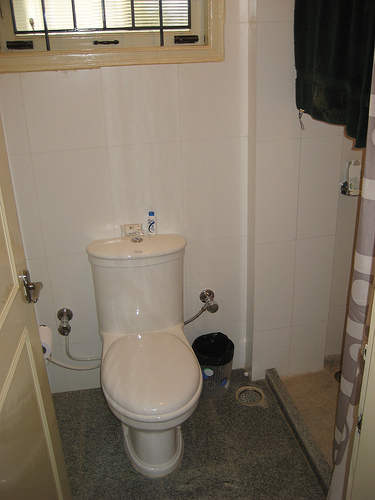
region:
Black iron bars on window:
[7, 0, 192, 34]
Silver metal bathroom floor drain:
[234, 385, 269, 410]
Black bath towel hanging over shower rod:
[294, 0, 373, 149]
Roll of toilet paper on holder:
[37, 323, 53, 357]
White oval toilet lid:
[100, 331, 199, 417]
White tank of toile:
[85, 233, 186, 327]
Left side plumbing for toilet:
[184, 288, 219, 326]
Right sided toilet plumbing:
[54, 307, 100, 362]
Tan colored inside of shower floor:
[281, 355, 348, 469]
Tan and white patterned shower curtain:
[327, 56, 374, 499]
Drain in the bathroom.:
[231, 382, 267, 412]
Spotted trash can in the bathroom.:
[193, 332, 246, 398]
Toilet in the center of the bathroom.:
[71, 224, 218, 488]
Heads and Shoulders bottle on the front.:
[141, 204, 162, 236]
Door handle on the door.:
[21, 271, 53, 313]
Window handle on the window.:
[90, 35, 126, 49]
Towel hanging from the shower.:
[297, 0, 368, 153]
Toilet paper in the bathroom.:
[40, 316, 55, 358]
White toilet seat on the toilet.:
[105, 331, 199, 416]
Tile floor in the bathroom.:
[222, 431, 273, 498]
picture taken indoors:
[36, 72, 313, 498]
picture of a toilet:
[41, 147, 247, 449]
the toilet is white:
[97, 227, 195, 472]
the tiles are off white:
[55, 103, 200, 181]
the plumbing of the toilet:
[54, 306, 94, 378]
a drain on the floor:
[236, 374, 272, 412]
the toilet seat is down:
[90, 325, 208, 413]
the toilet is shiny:
[123, 241, 155, 350]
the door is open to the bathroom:
[16, 312, 43, 423]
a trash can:
[206, 334, 225, 394]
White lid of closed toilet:
[97, 328, 203, 419]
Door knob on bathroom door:
[17, 271, 47, 305]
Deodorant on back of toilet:
[144, 210, 157, 236]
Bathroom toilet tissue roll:
[39, 326, 52, 358]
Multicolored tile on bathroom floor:
[226, 444, 277, 486]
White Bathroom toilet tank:
[82, 228, 190, 329]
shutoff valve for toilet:
[196, 290, 222, 316]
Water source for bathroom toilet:
[53, 308, 79, 339]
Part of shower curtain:
[348, 236, 368, 351]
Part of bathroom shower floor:
[309, 385, 327, 423]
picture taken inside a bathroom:
[18, 21, 359, 497]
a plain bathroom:
[18, 23, 293, 497]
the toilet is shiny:
[84, 237, 206, 443]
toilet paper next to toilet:
[38, 324, 60, 367]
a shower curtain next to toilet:
[335, 149, 363, 470]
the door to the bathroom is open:
[11, 163, 110, 481]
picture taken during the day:
[31, 2, 155, 17]